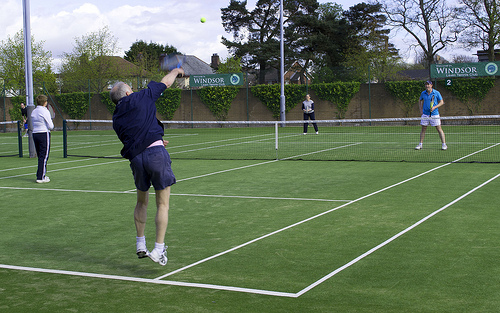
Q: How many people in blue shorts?
A: One.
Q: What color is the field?
A: Green.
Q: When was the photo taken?
A: Day time.